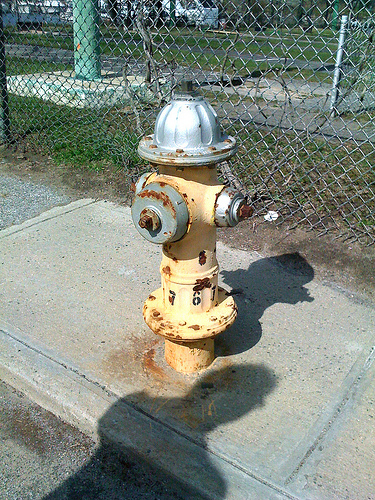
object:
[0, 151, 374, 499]
concrete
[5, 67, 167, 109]
base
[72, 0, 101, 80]
pole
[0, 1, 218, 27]
building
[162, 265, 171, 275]
rust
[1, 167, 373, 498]
gravel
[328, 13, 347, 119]
post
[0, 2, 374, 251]
fence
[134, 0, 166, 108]
vine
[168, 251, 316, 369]
shadow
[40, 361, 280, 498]
shadow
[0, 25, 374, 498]
ground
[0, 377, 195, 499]
gravel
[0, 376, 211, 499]
road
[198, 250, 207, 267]
rust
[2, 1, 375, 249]
doughnut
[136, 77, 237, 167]
top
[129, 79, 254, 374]
fire hydrant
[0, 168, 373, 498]
sidewalk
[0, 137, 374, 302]
dirt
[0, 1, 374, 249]
chainlink fence